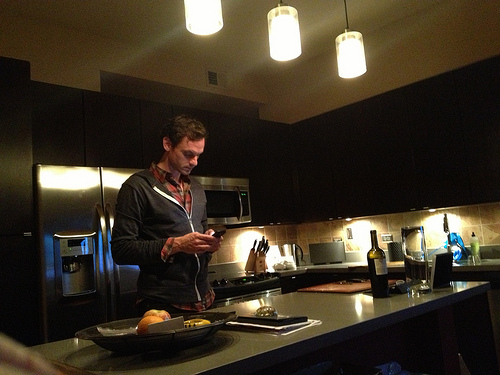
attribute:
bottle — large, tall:
[365, 229, 390, 300]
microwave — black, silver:
[186, 174, 253, 225]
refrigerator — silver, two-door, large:
[36, 162, 149, 342]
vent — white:
[204, 66, 232, 90]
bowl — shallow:
[74, 309, 239, 354]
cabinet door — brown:
[31, 80, 85, 167]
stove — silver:
[205, 261, 283, 305]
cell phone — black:
[212, 229, 227, 238]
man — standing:
[110, 116, 224, 317]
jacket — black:
[111, 168, 211, 303]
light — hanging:
[334, 0, 370, 81]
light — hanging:
[267, 1, 303, 63]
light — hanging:
[183, 2, 224, 38]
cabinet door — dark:
[83, 87, 144, 170]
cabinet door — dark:
[142, 98, 175, 172]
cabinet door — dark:
[173, 102, 212, 176]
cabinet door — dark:
[210, 111, 246, 177]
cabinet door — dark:
[241, 115, 298, 224]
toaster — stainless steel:
[307, 240, 347, 264]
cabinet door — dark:
[0, 54, 38, 236]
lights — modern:
[183, 1, 368, 79]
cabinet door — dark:
[290, 107, 336, 221]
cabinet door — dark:
[322, 101, 376, 218]